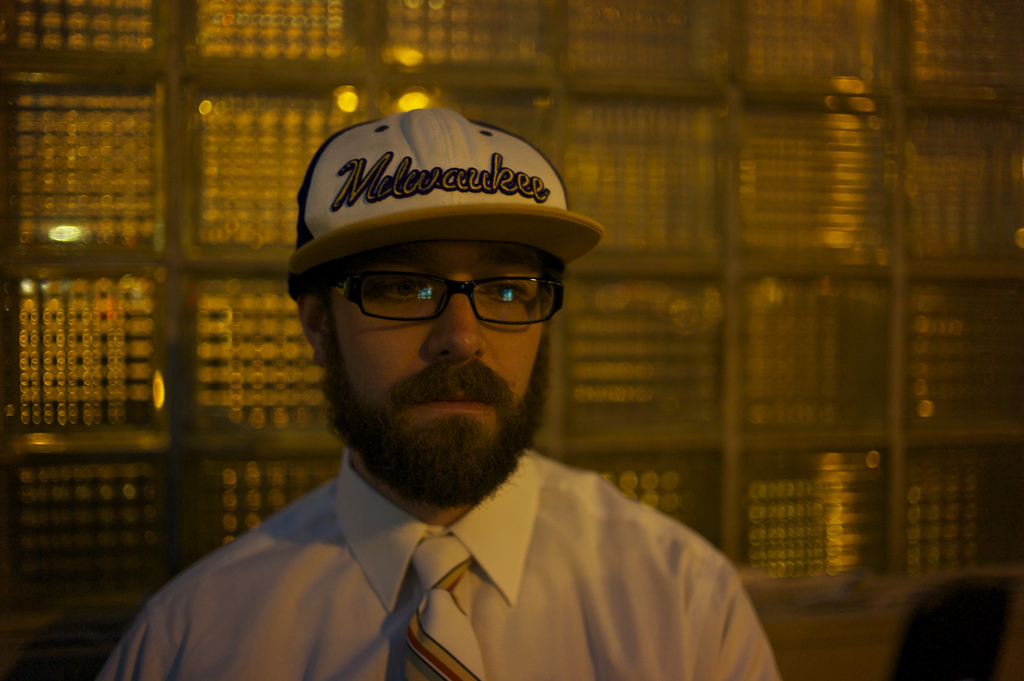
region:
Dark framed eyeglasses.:
[326, 262, 567, 332]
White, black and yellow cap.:
[288, 104, 603, 266]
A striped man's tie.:
[402, 529, 482, 678]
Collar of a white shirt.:
[326, 447, 545, 610]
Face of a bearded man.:
[304, 232, 554, 508]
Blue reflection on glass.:
[409, 281, 435, 305]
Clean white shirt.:
[98, 458, 798, 677]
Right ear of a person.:
[292, 286, 338, 364]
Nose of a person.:
[427, 299, 491, 370]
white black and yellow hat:
[279, 108, 615, 271]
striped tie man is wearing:
[398, 537, 479, 678]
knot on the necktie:
[410, 534, 467, 593]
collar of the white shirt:
[322, 437, 550, 603]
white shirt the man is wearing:
[104, 461, 779, 678]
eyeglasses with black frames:
[329, 267, 565, 332]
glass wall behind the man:
[6, 7, 1009, 666]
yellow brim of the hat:
[290, 200, 597, 258]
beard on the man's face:
[318, 288, 550, 500]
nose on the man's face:
[417, 288, 491, 362]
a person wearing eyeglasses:
[317, 252, 565, 338]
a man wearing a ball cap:
[286, 110, 600, 540]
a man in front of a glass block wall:
[7, 7, 1010, 678]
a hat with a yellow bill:
[288, 108, 605, 265]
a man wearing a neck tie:
[98, 101, 778, 672]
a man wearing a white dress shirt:
[112, 105, 783, 676]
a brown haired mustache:
[383, 353, 529, 415]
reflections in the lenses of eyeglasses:
[354, 266, 566, 325]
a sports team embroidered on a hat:
[326, 146, 593, 248]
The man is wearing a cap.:
[82, 98, 788, 678]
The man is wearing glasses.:
[85, 105, 793, 678]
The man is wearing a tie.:
[87, 102, 786, 678]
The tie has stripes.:
[388, 530, 494, 679]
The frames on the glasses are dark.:
[307, 253, 571, 326]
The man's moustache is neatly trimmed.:
[272, 97, 614, 524]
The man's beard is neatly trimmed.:
[274, 100, 611, 519]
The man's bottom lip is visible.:
[275, 97, 609, 510]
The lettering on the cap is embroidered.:
[281, 100, 610, 309]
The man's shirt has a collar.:
[92, 108, 785, 678]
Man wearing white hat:
[89, 86, 797, 675]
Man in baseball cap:
[89, 94, 773, 673]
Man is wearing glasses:
[84, 85, 832, 678]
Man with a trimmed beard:
[107, 82, 817, 678]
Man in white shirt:
[100, 110, 847, 677]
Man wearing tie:
[94, 105, 742, 662]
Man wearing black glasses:
[88, 88, 856, 678]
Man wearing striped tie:
[75, 88, 797, 673]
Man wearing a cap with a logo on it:
[114, 94, 810, 679]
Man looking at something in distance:
[104, 64, 833, 676]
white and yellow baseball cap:
[288, 108, 596, 270]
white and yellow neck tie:
[405, 527, 491, 679]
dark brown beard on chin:
[350, 423, 538, 500]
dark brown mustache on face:
[389, 358, 516, 407]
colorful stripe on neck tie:
[398, 626, 478, 678]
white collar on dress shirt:
[451, 500, 550, 593]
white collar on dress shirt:
[325, 478, 420, 605]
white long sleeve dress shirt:
[75, 486, 793, 677]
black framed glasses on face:
[341, 266, 564, 333]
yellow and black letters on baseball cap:
[328, 149, 554, 204]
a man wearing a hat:
[277, 19, 764, 667]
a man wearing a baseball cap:
[372, 124, 850, 586]